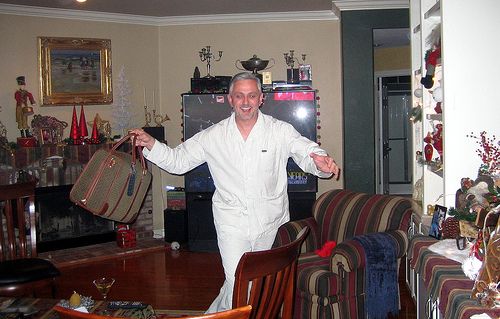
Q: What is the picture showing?
A: It is showing a living room.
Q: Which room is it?
A: It is a living room.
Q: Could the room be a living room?
A: Yes, it is a living room.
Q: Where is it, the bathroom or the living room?
A: It is the living room.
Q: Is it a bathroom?
A: No, it is a living room.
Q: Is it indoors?
A: Yes, it is indoors.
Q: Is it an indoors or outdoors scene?
A: It is indoors.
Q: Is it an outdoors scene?
A: No, it is indoors.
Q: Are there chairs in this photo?
A: Yes, there is a chair.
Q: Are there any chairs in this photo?
A: Yes, there is a chair.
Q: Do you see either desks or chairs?
A: Yes, there is a chair.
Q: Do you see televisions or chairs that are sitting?
A: Yes, the chair is sitting.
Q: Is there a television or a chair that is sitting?
A: Yes, the chair is sitting.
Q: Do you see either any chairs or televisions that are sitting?
A: Yes, the chair is sitting.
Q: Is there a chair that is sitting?
A: Yes, there is a chair that is sitting.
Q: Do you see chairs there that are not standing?
A: Yes, there is a chair that is sitting .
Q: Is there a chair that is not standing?
A: Yes, there is a chair that is sitting.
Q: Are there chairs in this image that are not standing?
A: Yes, there is a chair that is sitting.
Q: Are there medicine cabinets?
A: No, there are no medicine cabinets.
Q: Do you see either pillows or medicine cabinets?
A: No, there are no medicine cabinets or pillows.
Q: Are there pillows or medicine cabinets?
A: No, there are no medicine cabinets or pillows.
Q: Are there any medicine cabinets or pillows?
A: No, there are no medicine cabinets or pillows.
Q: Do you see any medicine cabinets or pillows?
A: No, there are no medicine cabinets or pillows.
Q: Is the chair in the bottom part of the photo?
A: Yes, the chair is in the bottom of the image.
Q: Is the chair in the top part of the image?
A: No, the chair is in the bottom of the image.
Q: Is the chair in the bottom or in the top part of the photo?
A: The chair is in the bottom of the image.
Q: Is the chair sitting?
A: Yes, the chair is sitting.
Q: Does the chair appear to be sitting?
A: Yes, the chair is sitting.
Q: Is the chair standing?
A: No, the chair is sitting.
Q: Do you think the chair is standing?
A: No, the chair is sitting.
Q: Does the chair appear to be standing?
A: No, the chair is sitting.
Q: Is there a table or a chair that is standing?
A: No, there is a chair but it is sitting.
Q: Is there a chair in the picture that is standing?
A: No, there is a chair but it is sitting.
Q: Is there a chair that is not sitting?
A: No, there is a chair but it is sitting.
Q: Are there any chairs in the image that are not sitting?
A: No, there is a chair but it is sitting.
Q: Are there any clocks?
A: No, there are no clocks.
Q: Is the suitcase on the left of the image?
A: Yes, the suitcase is on the left of the image.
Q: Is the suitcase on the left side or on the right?
A: The suitcase is on the left of the image.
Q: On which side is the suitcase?
A: The suitcase is on the left of the image.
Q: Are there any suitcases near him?
A: Yes, there is a suitcase near the man.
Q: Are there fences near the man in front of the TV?
A: No, there is a suitcase near the man.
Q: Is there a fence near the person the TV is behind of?
A: No, there is a suitcase near the man.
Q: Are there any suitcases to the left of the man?
A: Yes, there is a suitcase to the left of the man.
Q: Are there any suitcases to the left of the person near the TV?
A: Yes, there is a suitcase to the left of the man.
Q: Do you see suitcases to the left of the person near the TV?
A: Yes, there is a suitcase to the left of the man.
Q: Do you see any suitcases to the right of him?
A: No, the suitcase is to the left of the man.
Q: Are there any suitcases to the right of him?
A: No, the suitcase is to the left of the man.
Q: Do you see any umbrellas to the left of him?
A: No, there is a suitcase to the left of the man.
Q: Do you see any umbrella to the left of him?
A: No, there is a suitcase to the left of the man.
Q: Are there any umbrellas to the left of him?
A: No, there is a suitcase to the left of the man.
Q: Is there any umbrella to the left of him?
A: No, there is a suitcase to the left of the man.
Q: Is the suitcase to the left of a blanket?
A: No, the suitcase is to the left of the man.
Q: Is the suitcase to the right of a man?
A: No, the suitcase is to the left of a man.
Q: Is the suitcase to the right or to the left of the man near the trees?
A: The suitcase is to the left of the man.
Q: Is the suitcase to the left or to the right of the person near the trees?
A: The suitcase is to the left of the man.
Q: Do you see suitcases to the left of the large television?
A: Yes, there is a suitcase to the left of the television.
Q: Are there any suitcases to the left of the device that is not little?
A: Yes, there is a suitcase to the left of the television.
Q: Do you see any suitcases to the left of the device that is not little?
A: Yes, there is a suitcase to the left of the television.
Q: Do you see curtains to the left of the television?
A: No, there is a suitcase to the left of the television.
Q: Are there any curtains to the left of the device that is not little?
A: No, there is a suitcase to the left of the television.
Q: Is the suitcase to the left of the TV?
A: Yes, the suitcase is to the left of the TV.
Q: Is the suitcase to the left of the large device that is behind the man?
A: Yes, the suitcase is to the left of the TV.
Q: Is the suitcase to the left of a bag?
A: No, the suitcase is to the left of the TV.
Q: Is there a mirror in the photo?
A: No, there are no mirrors.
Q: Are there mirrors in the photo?
A: No, there are no mirrors.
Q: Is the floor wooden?
A: Yes, the floor is wooden.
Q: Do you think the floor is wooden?
A: Yes, the floor is wooden.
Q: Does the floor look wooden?
A: Yes, the floor is wooden.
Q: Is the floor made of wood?
A: Yes, the floor is made of wood.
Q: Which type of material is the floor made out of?
A: The floor is made of wood.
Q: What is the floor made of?
A: The floor is made of wood.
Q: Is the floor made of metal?
A: No, the floor is made of wood.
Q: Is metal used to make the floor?
A: No, the floor is made of wood.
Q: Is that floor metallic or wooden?
A: The floor is wooden.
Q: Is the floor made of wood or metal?
A: The floor is made of wood.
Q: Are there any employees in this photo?
A: No, there are no employees.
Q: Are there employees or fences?
A: No, there are no employees or fences.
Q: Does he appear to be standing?
A: Yes, the man is standing.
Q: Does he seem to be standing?
A: Yes, the man is standing.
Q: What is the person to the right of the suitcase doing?
A: The man is standing.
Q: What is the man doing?
A: The man is standing.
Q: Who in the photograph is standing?
A: The man is standing.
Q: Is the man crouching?
A: No, the man is standing.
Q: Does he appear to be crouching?
A: No, the man is standing.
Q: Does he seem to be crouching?
A: No, the man is standing.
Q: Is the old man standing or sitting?
A: The man is standing.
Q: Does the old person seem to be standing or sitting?
A: The man is standing.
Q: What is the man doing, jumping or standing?
A: The man is standing.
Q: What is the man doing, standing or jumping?
A: The man is standing.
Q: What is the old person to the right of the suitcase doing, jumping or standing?
A: The man is standing.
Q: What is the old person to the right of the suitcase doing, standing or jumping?
A: The man is standing.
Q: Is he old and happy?
A: Yes, the man is old and happy.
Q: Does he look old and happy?
A: Yes, the man is old and happy.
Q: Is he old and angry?
A: No, the man is old but happy.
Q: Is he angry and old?
A: No, the man is old but happy.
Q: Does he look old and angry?
A: No, the man is old but happy.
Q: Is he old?
A: Yes, the man is old.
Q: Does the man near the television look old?
A: Yes, the man is old.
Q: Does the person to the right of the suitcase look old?
A: Yes, the man is old.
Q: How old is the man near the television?
A: The man is old.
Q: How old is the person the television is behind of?
A: The man is old.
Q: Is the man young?
A: No, the man is old.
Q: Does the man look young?
A: No, the man is old.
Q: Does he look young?
A: No, the man is old.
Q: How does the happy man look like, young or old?
A: The man is old.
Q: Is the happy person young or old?
A: The man is old.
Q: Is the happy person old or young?
A: The man is old.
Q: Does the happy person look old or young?
A: The man is old.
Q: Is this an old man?
A: Yes, this is an old man.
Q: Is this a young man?
A: No, this is an old man.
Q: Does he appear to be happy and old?
A: Yes, the man is happy and old.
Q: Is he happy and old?
A: Yes, the man is happy and old.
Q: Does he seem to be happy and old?
A: Yes, the man is happy and old.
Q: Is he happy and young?
A: No, the man is happy but old.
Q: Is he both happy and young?
A: No, the man is happy but old.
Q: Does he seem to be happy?
A: Yes, the man is happy.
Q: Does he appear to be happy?
A: Yes, the man is happy.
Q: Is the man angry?
A: No, the man is happy.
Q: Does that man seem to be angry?
A: No, the man is happy.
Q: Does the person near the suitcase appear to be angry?
A: No, the man is happy.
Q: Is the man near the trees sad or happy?
A: The man is happy.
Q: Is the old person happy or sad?
A: The man is happy.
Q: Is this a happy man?
A: Yes, this is a happy man.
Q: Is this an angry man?
A: No, this is a happy man.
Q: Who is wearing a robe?
A: The man is wearing a robe.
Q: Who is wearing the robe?
A: The man is wearing a robe.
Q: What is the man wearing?
A: The man is wearing a robe.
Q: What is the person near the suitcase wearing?
A: The man is wearing a robe.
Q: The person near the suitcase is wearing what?
A: The man is wearing a robe.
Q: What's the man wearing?
A: The man is wearing a robe.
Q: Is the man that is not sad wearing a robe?
A: Yes, the man is wearing a robe.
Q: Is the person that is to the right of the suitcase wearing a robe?
A: Yes, the man is wearing a robe.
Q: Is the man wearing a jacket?
A: No, the man is wearing a robe.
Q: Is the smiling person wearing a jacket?
A: No, the man is wearing a robe.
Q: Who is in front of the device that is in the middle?
A: The man is in front of the television.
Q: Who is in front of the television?
A: The man is in front of the television.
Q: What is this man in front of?
A: The man is in front of the television.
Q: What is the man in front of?
A: The man is in front of the television.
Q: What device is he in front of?
A: The man is in front of the television.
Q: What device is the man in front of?
A: The man is in front of the television.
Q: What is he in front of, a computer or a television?
A: The man is in front of a television.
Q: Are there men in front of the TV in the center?
A: Yes, there is a man in front of the television.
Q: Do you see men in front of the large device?
A: Yes, there is a man in front of the television.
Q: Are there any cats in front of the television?
A: No, there is a man in front of the television.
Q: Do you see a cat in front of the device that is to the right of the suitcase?
A: No, there is a man in front of the television.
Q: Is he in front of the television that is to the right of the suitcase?
A: Yes, the man is in front of the television.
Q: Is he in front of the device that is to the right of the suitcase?
A: Yes, the man is in front of the television.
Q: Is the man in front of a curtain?
A: No, the man is in front of the television.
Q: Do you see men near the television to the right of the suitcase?
A: Yes, there is a man near the television.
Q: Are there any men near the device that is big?
A: Yes, there is a man near the television.